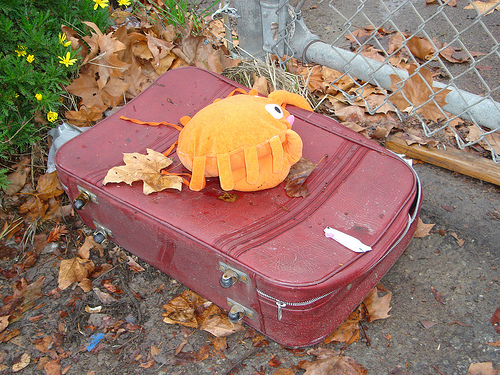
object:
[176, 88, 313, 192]
stuffed animal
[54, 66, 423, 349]
suitcase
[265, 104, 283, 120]
eye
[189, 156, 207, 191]
leg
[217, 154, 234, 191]
leg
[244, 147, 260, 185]
leg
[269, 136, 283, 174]
leg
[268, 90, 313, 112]
leg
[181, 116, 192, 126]
leg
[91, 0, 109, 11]
flower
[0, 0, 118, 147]
grass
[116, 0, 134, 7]
flower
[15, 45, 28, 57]
flower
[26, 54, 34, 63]
flower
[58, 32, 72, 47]
flower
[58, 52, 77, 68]
flower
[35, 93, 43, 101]
flower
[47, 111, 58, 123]
flower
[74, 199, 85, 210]
wheel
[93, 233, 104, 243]
wheel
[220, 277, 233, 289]
wheel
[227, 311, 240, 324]
wheel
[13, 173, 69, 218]
leaf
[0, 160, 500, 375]
ground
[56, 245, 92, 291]
leaf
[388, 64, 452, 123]
leaf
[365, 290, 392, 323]
leaf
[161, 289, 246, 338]
leaf